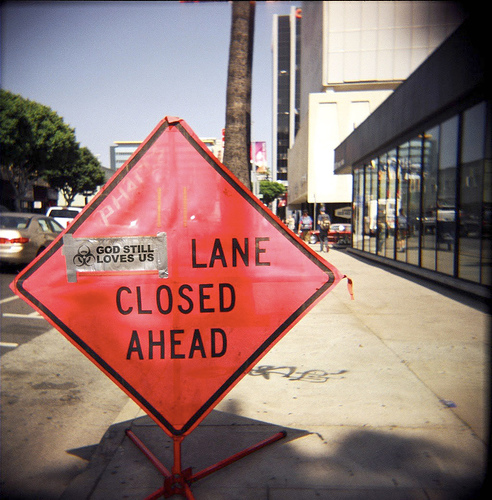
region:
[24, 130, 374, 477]
road warning is red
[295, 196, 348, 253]
people walking at the sidewalk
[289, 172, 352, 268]
people walking at the sidewalk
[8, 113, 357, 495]
An orange traffic sign.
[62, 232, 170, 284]
A sign taped to a sign.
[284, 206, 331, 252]
People walking on the sidewalk.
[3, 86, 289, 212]
Trees on the sidewalk.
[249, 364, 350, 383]
Graffiti on the sidewalk.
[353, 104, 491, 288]
Windows on a building.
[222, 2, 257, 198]
A brown tree trunk.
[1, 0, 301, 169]
A clear blue sky.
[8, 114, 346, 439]
A triangle shaped sign.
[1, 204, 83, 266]
Cars on the street.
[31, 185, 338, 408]
red and black construction sign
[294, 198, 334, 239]
two people walking on a sidewalk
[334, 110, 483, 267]
a building with several large windows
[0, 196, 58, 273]
a car on the road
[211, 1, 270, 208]
a tall tree next to a road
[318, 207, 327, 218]
a man wearing a hat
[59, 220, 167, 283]
a sticker on a sign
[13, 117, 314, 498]
a construction sign on a stand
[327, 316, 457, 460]
concrete sidewalk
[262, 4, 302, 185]
a tall building with several levels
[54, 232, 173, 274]
white and black sticker on traffic sign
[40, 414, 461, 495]
shadows on the sidewalk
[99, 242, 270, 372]
black lettering on orange sign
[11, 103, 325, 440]
orange sign with black border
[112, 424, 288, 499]
orange base of sign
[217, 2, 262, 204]
tree trunk behind orange sign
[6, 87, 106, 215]
trees along the street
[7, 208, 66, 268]
tan car driving down street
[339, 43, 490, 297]
building alongside the sidewalk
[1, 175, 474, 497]
sidewalk orange sign is on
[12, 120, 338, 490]
lane closed sign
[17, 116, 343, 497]
orange constuctio warning sign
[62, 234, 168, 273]
sticker stuck on orange construction sign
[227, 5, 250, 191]
tree trunk directly behind the sign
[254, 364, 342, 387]
black graffiti on the sidewalk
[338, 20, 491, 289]
long store front with all glass windows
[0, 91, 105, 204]
trees across the street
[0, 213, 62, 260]
gold colored car in the road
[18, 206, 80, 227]
white pick-up truck in the road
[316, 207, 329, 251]
person with a beige backpack